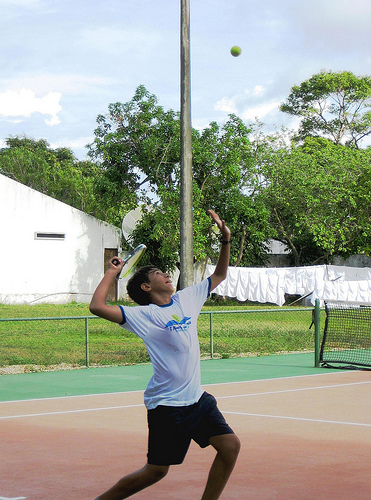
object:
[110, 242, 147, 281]
tennis racket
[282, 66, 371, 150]
tree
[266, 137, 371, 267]
tree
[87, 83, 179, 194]
tree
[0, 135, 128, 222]
tree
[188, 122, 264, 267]
tree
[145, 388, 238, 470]
shorts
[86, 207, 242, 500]
boy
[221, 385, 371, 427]
lines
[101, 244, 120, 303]
door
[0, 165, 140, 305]
house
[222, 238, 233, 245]
black watch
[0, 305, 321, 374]
fence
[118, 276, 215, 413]
shirt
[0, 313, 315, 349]
dirt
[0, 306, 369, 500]
court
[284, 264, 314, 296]
clothes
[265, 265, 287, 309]
clothes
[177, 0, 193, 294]
pole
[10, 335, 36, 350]
chain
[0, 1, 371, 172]
air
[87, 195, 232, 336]
upward